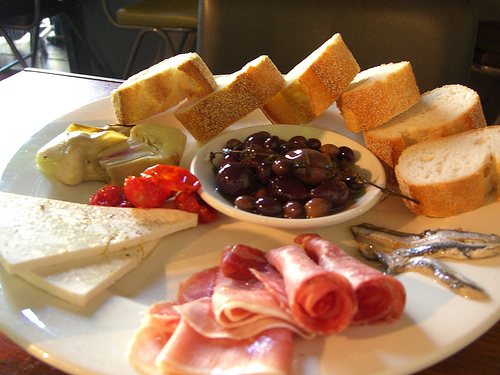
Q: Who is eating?
A: No one.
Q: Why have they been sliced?
A: For easy eating.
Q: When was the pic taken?
A: During the day.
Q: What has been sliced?
A: Bread.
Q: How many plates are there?
A: 1.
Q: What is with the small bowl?
A: Grapes.